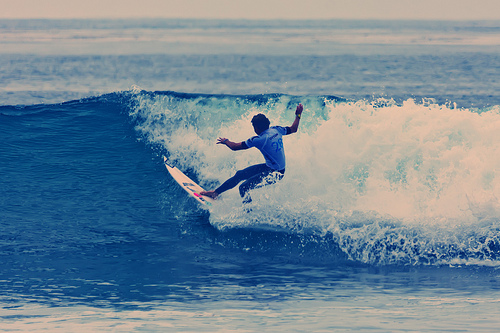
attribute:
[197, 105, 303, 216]
man — surfing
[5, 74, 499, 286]
wave — dark blue, white, broken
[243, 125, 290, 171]
top — short sleeved, rashguard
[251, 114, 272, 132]
head — curly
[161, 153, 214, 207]
surfboard — white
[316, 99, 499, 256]
water — white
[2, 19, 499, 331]
water — rough, still, blue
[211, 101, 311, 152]
arms — extended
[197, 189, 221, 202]
right foot — forward